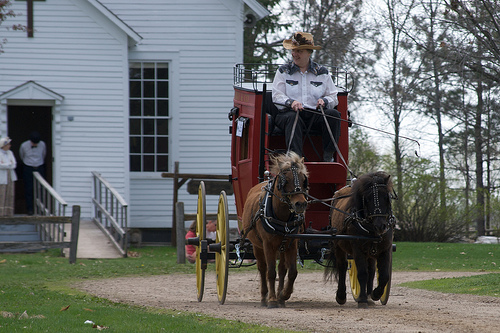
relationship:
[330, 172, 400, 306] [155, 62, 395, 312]
horse attached to cart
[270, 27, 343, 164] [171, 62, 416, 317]
man on couch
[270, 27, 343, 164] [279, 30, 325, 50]
man wearing a cowboy hat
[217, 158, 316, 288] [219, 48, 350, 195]
horse attached to cart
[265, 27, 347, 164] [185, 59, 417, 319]
man drives carriage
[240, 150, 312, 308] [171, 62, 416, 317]
horse pull couch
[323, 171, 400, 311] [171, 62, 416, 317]
horse pull couch